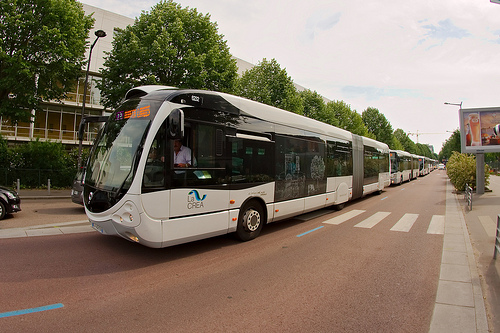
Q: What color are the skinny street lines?
A: Blue.